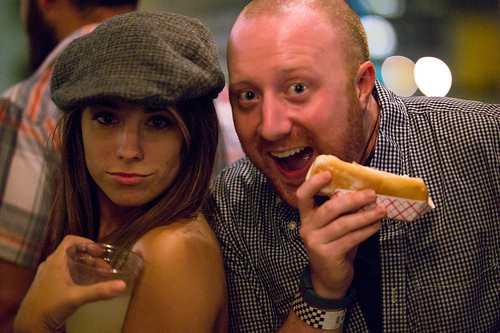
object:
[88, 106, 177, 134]
eyes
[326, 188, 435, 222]
basket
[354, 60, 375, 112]
ear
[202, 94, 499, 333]
dressing shirt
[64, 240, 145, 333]
beverage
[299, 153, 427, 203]
hotdog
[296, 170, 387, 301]
hand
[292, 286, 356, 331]
band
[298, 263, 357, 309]
watch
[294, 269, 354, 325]
wrist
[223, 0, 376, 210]
head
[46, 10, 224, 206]
head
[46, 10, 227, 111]
hat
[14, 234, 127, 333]
hand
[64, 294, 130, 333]
liquid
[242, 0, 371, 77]
hair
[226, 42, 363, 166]
man's face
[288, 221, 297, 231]
button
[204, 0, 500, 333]
man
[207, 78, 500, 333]
shirt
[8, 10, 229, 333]
girl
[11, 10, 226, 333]
woman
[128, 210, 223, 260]
shoulder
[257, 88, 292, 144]
nose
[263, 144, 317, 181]
mouth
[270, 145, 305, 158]
teeth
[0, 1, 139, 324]
man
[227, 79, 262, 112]
eye